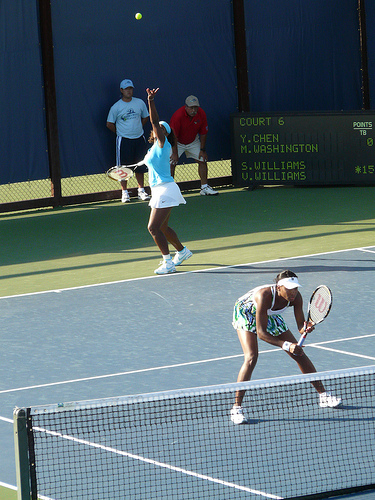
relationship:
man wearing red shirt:
[169, 94, 219, 197] [165, 107, 209, 146]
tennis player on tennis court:
[141, 86, 193, 275] [0, 0, 374, 499]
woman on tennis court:
[229, 269, 342, 426] [0, 0, 374, 499]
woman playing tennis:
[229, 269, 342, 426] [293, 282, 338, 374]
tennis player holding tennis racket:
[141, 86, 193, 275] [105, 158, 143, 182]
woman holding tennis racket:
[229, 269, 342, 426] [297, 282, 334, 348]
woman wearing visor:
[126, 85, 203, 275] [158, 117, 174, 134]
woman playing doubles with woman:
[229, 269, 342, 426] [135, 85, 192, 277]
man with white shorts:
[169, 94, 219, 197] [173, 135, 203, 163]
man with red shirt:
[169, 94, 219, 197] [165, 107, 209, 146]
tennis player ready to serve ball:
[141, 86, 193, 275] [134, 9, 142, 19]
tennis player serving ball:
[141, 86, 193, 275] [130, 9, 145, 21]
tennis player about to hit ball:
[141, 86, 193, 275] [133, 11, 142, 20]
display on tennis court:
[232, 115, 374, 185] [0, 187, 373, 498]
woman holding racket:
[229, 269, 342, 426] [290, 276, 333, 352]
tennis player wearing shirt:
[141, 86, 193, 275] [140, 133, 175, 188]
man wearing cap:
[154, 94, 222, 200] [183, 93, 202, 110]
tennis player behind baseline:
[123, 86, 194, 274] [0, 241, 374, 298]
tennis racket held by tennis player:
[105, 158, 143, 181] [141, 86, 193, 275]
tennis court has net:
[0, 187, 373, 498] [11, 362, 374, 499]